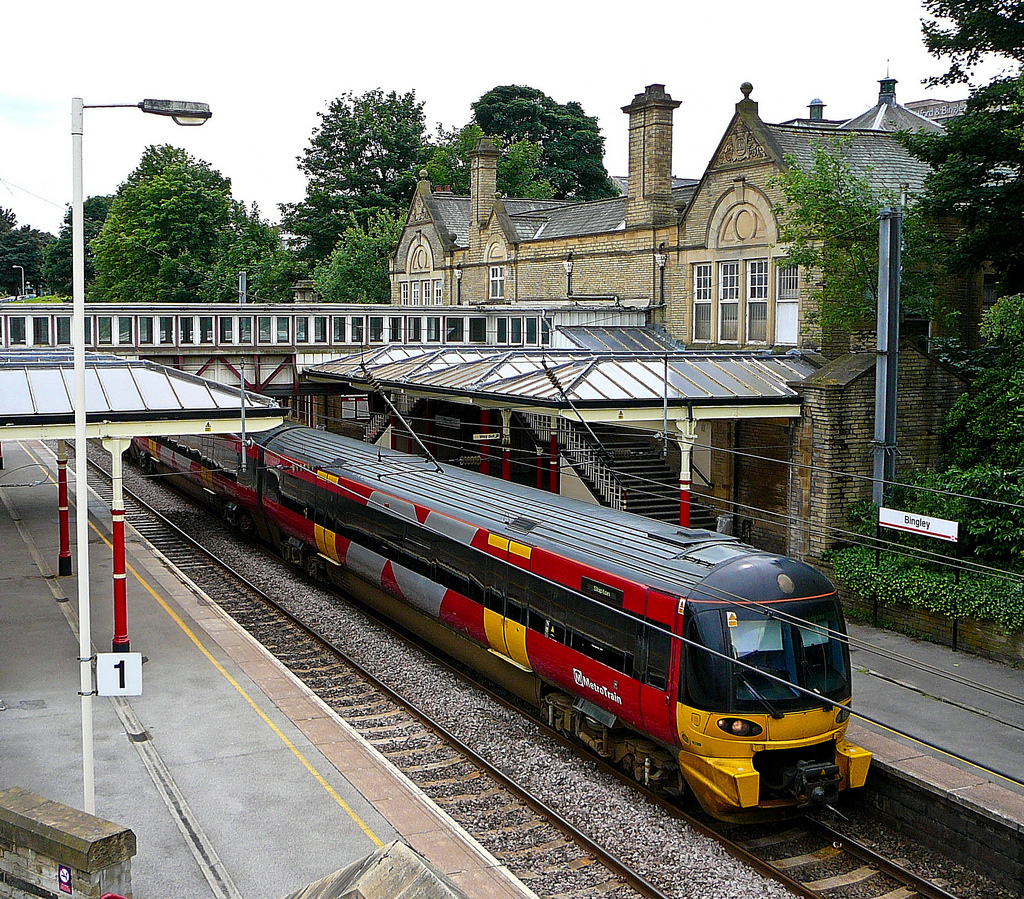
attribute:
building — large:
[396, 94, 989, 462]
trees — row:
[93, 68, 610, 295]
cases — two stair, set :
[585, 422, 758, 533]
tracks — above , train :
[793, 826, 904, 889]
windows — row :
[389, 528, 685, 675]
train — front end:
[166, 420, 873, 829]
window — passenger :
[542, 597, 640, 660]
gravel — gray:
[562, 786, 699, 886]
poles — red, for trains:
[30, 490, 171, 659]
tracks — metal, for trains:
[184, 512, 480, 763]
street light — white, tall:
[41, 78, 117, 774]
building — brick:
[527, 177, 916, 409]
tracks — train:
[302, 637, 819, 869]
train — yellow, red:
[235, 410, 929, 834]